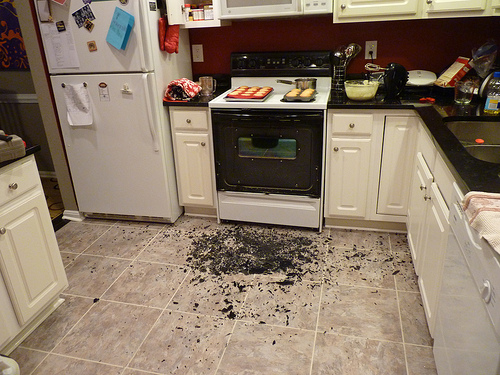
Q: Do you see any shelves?
A: No, there are no shelves.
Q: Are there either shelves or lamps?
A: No, there are no shelves or lamps.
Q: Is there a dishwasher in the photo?
A: Yes, there is a dishwasher.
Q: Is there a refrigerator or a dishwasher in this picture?
A: Yes, there is a dishwasher.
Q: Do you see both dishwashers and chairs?
A: No, there is a dishwasher but no chairs.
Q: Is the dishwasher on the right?
A: Yes, the dishwasher is on the right of the image.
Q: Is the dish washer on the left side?
A: No, the dish washer is on the right of the image.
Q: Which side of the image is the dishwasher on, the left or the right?
A: The dishwasher is on the right of the image.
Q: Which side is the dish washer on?
A: The dish washer is on the right of the image.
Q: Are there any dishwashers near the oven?
A: Yes, there is a dishwasher near the oven.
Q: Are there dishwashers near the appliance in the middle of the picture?
A: Yes, there is a dishwasher near the oven.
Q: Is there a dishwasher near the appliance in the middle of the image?
A: Yes, there is a dishwasher near the oven.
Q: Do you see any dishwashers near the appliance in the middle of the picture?
A: Yes, there is a dishwasher near the oven.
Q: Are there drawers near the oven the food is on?
A: No, there is a dishwasher near the oven.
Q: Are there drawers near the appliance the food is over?
A: No, there is a dishwasher near the oven.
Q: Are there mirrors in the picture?
A: No, there are no mirrors.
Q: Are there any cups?
A: Yes, there is a cup.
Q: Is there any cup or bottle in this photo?
A: Yes, there is a cup.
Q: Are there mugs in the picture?
A: No, there are no mugs.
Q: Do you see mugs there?
A: No, there are no mugs.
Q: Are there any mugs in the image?
A: No, there are no mugs.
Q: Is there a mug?
A: No, there are no mugs.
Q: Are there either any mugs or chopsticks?
A: No, there are no mugs or chopsticks.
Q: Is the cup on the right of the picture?
A: Yes, the cup is on the right of the image.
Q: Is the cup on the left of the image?
A: No, the cup is on the right of the image.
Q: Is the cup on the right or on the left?
A: The cup is on the right of the image.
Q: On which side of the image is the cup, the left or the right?
A: The cup is on the right of the image.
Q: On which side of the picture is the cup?
A: The cup is on the right of the image.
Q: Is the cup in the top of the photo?
A: Yes, the cup is in the top of the image.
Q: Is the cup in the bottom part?
A: No, the cup is in the top of the image.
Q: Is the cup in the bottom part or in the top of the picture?
A: The cup is in the top of the image.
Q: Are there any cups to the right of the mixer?
A: Yes, there is a cup to the right of the mixer.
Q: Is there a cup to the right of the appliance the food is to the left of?
A: Yes, there is a cup to the right of the mixer.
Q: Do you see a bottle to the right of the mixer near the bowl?
A: No, there is a cup to the right of the mixer.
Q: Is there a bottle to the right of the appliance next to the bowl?
A: No, there is a cup to the right of the mixer.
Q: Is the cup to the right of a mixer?
A: Yes, the cup is to the right of a mixer.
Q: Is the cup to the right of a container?
A: No, the cup is to the right of a mixer.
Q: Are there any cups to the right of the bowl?
A: Yes, there is a cup to the right of the bowl.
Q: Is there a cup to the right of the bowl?
A: Yes, there is a cup to the right of the bowl.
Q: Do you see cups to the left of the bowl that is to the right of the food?
A: No, the cup is to the right of the bowl.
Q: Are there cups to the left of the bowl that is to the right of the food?
A: No, the cup is to the right of the bowl.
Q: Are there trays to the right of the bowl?
A: No, there is a cup to the right of the bowl.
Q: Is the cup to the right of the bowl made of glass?
A: Yes, the cup is to the right of the bowl.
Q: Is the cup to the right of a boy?
A: No, the cup is to the right of the bowl.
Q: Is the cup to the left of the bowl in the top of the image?
A: No, the cup is to the right of the bowl.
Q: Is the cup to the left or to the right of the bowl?
A: The cup is to the right of the bowl.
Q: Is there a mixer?
A: Yes, there is a mixer.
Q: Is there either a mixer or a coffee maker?
A: Yes, there is a mixer.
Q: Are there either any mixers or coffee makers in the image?
A: Yes, there is a mixer.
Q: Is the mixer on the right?
A: Yes, the mixer is on the right of the image.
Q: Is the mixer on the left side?
A: No, the mixer is on the right of the image.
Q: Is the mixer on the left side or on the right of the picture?
A: The mixer is on the right of the image.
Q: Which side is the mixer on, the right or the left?
A: The mixer is on the right of the image.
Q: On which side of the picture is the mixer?
A: The mixer is on the right of the image.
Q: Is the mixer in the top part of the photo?
A: Yes, the mixer is in the top of the image.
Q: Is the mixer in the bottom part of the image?
A: No, the mixer is in the top of the image.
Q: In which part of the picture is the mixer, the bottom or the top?
A: The mixer is in the top of the image.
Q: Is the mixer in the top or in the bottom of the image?
A: The mixer is in the top of the image.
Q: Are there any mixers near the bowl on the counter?
A: Yes, there is a mixer near the bowl.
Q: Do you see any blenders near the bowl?
A: No, there is a mixer near the bowl.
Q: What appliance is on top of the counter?
A: The appliance is a mixer.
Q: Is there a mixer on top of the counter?
A: Yes, there is a mixer on top of the counter.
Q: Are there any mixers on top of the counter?
A: Yes, there is a mixer on top of the counter.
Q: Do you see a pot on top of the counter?
A: No, there is a mixer on top of the counter.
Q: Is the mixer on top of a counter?
A: Yes, the mixer is on top of a counter.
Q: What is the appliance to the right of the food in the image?
A: The appliance is a mixer.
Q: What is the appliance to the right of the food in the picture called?
A: The appliance is a mixer.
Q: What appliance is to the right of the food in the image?
A: The appliance is a mixer.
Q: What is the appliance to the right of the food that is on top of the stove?
A: The appliance is a mixer.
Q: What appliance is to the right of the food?
A: The appliance is a mixer.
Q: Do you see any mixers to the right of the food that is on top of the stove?
A: Yes, there is a mixer to the right of the food.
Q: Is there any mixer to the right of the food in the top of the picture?
A: Yes, there is a mixer to the right of the food.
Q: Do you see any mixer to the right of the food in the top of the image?
A: Yes, there is a mixer to the right of the food.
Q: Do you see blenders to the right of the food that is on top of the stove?
A: No, there is a mixer to the right of the food.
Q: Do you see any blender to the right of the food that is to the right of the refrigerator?
A: No, there is a mixer to the right of the food.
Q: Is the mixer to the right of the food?
A: Yes, the mixer is to the right of the food.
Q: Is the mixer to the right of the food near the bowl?
A: Yes, the mixer is to the right of the food.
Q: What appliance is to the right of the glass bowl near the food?
A: The appliance is a mixer.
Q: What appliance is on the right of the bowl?
A: The appliance is a mixer.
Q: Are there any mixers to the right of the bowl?
A: Yes, there is a mixer to the right of the bowl.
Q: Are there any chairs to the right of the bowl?
A: No, there is a mixer to the right of the bowl.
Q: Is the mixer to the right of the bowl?
A: Yes, the mixer is to the right of the bowl.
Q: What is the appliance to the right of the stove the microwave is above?
A: The appliance is a mixer.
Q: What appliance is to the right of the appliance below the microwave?
A: The appliance is a mixer.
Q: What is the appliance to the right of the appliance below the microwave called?
A: The appliance is a mixer.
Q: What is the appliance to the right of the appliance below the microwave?
A: The appliance is a mixer.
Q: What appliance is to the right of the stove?
A: The appliance is a mixer.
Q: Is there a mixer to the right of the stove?
A: Yes, there is a mixer to the right of the stove.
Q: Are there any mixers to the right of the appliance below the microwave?
A: Yes, there is a mixer to the right of the stove.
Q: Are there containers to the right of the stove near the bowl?
A: No, there is a mixer to the right of the stove.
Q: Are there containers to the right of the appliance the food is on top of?
A: No, there is a mixer to the right of the stove.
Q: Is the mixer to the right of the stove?
A: Yes, the mixer is to the right of the stove.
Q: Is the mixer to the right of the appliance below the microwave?
A: Yes, the mixer is to the right of the stove.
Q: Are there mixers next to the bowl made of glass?
A: Yes, there is a mixer next to the bowl.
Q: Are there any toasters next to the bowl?
A: No, there is a mixer next to the bowl.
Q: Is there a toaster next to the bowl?
A: No, there is a mixer next to the bowl.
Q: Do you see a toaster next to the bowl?
A: No, there is a mixer next to the bowl.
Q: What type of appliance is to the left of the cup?
A: The appliance is a mixer.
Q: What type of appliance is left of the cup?
A: The appliance is a mixer.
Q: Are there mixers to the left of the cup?
A: Yes, there is a mixer to the left of the cup.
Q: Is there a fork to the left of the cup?
A: No, there is a mixer to the left of the cup.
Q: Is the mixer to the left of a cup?
A: Yes, the mixer is to the left of a cup.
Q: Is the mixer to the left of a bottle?
A: No, the mixer is to the left of a cup.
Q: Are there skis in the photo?
A: No, there are no skis.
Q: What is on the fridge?
A: The paper is on the fridge.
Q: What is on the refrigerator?
A: The paper is on the fridge.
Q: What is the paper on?
A: The paper is on the fridge.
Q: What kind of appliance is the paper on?
A: The paper is on the freezer.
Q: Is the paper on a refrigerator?
A: Yes, the paper is on a refrigerator.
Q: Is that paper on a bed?
A: No, the paper is on a refrigerator.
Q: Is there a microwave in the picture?
A: Yes, there is a microwave.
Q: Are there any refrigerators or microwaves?
A: Yes, there is a microwave.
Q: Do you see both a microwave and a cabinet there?
A: Yes, there are both a microwave and a cabinet.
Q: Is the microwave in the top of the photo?
A: Yes, the microwave is in the top of the image.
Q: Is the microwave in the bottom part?
A: No, the microwave is in the top of the image.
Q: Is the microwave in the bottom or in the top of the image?
A: The microwave is in the top of the image.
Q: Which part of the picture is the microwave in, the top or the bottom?
A: The microwave is in the top of the image.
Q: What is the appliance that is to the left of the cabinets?
A: The appliance is a microwave.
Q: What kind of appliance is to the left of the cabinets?
A: The appliance is a microwave.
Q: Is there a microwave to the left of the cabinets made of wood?
A: Yes, there is a microwave to the left of the cabinets.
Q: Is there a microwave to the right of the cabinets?
A: No, the microwave is to the left of the cabinets.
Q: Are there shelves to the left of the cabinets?
A: No, there is a microwave to the left of the cabinets.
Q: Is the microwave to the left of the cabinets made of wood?
A: Yes, the microwave is to the left of the cabinets.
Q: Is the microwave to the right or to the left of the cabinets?
A: The microwave is to the left of the cabinets.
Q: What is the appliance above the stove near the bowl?
A: The appliance is a microwave.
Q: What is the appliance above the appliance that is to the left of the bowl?
A: The appliance is a microwave.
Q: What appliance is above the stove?
A: The appliance is a microwave.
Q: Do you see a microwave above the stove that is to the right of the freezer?
A: Yes, there is a microwave above the stove.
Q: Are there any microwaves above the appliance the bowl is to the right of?
A: Yes, there is a microwave above the stove.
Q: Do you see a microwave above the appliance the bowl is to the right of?
A: Yes, there is a microwave above the stove.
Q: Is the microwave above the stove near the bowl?
A: Yes, the microwave is above the stove.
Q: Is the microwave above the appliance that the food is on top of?
A: Yes, the microwave is above the stove.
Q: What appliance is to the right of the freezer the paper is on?
A: The appliance is a microwave.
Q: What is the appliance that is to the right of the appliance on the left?
A: The appliance is a microwave.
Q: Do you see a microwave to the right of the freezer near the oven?
A: Yes, there is a microwave to the right of the refrigerator.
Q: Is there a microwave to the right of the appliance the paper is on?
A: Yes, there is a microwave to the right of the refrigerator.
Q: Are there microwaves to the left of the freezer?
A: No, the microwave is to the right of the freezer.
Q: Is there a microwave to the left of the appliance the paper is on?
A: No, the microwave is to the right of the freezer.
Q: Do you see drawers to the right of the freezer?
A: No, there is a microwave to the right of the freezer.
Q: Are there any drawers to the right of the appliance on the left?
A: No, there is a microwave to the right of the freezer.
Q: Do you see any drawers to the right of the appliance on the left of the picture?
A: No, there is a microwave to the right of the freezer.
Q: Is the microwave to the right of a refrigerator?
A: Yes, the microwave is to the right of a refrigerator.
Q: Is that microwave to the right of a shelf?
A: No, the microwave is to the right of a refrigerator.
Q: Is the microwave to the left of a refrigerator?
A: No, the microwave is to the right of a refrigerator.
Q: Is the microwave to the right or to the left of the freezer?
A: The microwave is to the right of the freezer.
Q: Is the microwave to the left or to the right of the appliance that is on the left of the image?
A: The microwave is to the right of the freezer.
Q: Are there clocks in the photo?
A: No, there are no clocks.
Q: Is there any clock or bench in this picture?
A: No, there are no clocks or benches.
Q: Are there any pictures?
A: No, there are no pictures.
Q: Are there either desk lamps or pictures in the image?
A: No, there are no pictures or desk lamps.